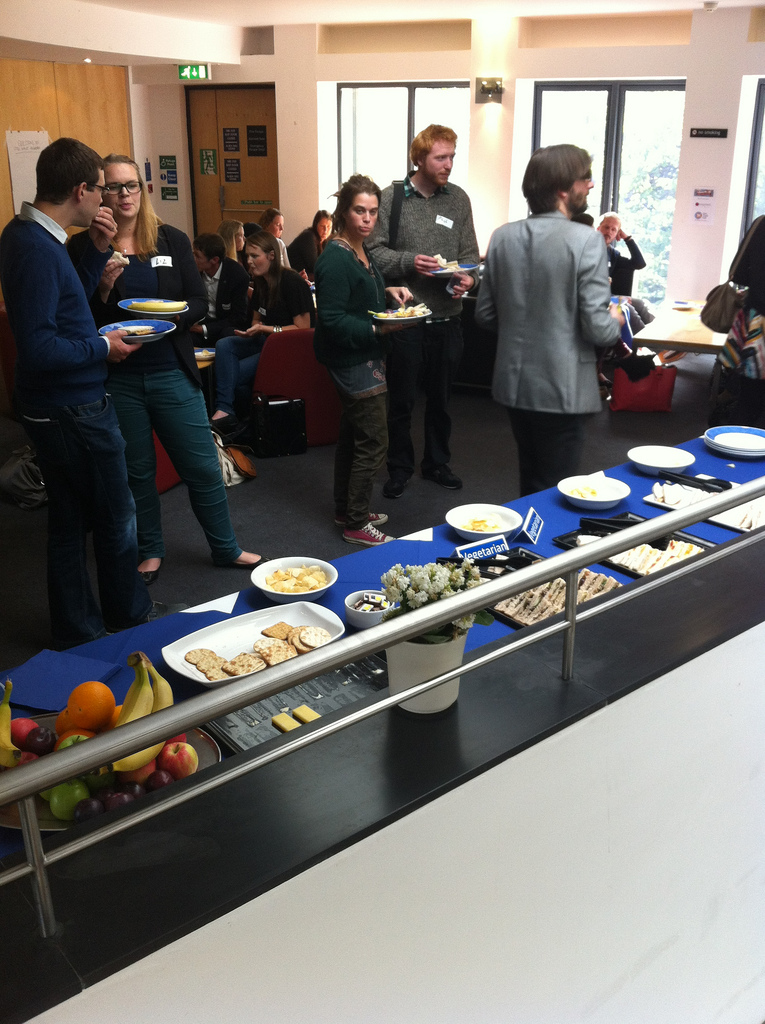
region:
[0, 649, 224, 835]
metal platter of fruits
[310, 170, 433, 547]
woman wearing red shoes holding a plate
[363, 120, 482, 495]
man wearing a gray sweater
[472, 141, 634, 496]
man wearing cheap gray jacket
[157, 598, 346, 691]
white tray with crackers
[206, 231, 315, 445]
woman wearing a black shirt sitting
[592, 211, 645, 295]
man sitting in front of a window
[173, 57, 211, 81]
green and white sign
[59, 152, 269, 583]
woman with blonde hair wearing blue pants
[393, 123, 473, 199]
the head of a man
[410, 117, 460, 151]
the hair of a man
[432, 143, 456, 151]
the forehead of a man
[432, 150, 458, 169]
the eyes of a man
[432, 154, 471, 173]
the nose of a man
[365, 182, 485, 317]
the shirt of a man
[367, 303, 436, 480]
the right leg of a man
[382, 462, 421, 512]
the right foot of a man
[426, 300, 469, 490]
the left leg of a man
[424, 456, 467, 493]
the left foot of a man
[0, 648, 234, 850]
bowl of fruit on counter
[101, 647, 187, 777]
banana bunch in bowl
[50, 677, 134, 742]
oranges in fruit bowl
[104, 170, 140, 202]
woman wearing pair of glasses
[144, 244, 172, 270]
name tag on woman's shirt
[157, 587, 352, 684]
white plate of crackers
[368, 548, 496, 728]
flower pot on counter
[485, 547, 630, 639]
plate of sandwich slices on counter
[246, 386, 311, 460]
hand bag on floor by chair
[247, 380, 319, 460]
hand bag on floor is black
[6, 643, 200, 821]
various fruits on the tray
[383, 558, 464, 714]
white flowers in a container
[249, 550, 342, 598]
chips in a white bowl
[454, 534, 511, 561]
place cards on the table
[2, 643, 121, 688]
blue napkins on the table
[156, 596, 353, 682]
crackers in a white dish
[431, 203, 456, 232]
name tag on the shirt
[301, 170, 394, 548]
woman with a plate of food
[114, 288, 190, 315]
yellow banana on the plate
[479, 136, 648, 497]
a person is standing up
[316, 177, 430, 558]
a person is standing up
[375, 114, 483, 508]
a person is standing up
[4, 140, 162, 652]
a person is standing up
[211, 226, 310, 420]
a person is sitting down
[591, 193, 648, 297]
a person is sitting down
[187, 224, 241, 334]
a person is sitting down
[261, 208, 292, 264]
a person is sitting down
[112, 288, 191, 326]
blue plate held by woman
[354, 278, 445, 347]
blue plate held by woman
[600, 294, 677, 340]
blue plate held by man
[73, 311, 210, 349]
blue plate held by man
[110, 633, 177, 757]
yellow bananas on blue cloth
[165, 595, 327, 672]
white container holding food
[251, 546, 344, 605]
white container holding food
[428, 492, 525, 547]
white container holding food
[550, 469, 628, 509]
white container holding food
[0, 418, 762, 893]
counter filled with food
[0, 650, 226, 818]
platter filled with a variety of fruit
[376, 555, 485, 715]
small white pot of planted flowers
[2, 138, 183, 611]
man holding a plate of food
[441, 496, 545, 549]
blue and white sign near a bowl